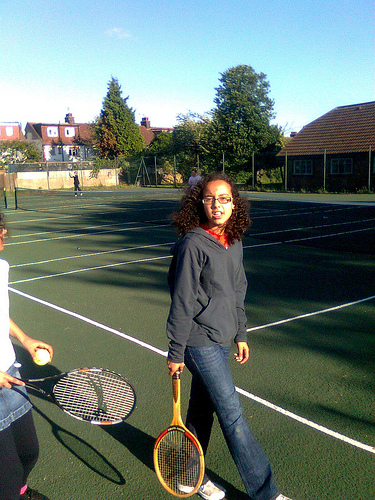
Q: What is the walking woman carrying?
A: Racquet.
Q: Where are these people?
A: Court.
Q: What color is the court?
A: Green.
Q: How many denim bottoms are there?
A: 2.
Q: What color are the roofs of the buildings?
A: Red.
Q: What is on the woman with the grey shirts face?
A: Glasses.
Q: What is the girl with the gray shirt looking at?
A: Camera.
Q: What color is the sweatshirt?
A: Gray.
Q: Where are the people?
A: Tennis Court.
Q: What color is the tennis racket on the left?
A: Black.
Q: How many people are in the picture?
A: Four.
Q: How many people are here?
A: 3.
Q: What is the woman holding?
A: Racket.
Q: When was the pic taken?
A: During the day.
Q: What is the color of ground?
A: Green.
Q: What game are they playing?
A: Tennis.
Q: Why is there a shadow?
A: The sun is high.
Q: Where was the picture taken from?
A: At a tennis court.